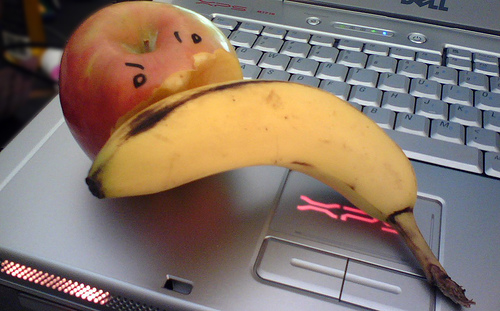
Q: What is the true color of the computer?
A: Gray.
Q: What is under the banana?
A: Laptop.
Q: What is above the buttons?
A: Touchpad.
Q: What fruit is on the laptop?
A: Apple and banana.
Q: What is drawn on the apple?
A: Eyes.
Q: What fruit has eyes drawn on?
A: Apple.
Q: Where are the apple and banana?
A: On a laptop computer.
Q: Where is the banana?
A: Next to the apple.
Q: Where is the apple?
A: Left from banana.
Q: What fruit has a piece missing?
A: Apple.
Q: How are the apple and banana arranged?
A: Apple is biting banana.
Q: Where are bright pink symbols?
A: On the laptop touchpad.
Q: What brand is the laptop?
A: Dell.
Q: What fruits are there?
A: Banana/apple.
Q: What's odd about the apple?
A: Drawn on.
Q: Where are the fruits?
A: On laptop.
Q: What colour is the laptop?
A: Silver.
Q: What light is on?
A: Laptop light.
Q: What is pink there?
A: Letters.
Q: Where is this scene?
A: Bedroom.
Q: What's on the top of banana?
A: Stem.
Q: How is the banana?
A: Ripe.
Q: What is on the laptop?
A: An apple and a banana.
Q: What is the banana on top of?
A: The laptop's trackpad.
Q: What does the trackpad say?
A: XPS.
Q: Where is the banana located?
A: In front of the apple.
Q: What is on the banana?
A: Brown spots.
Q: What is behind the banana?
A: An apple.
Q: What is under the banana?
A: A laptop.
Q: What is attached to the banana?
A: The banana stem.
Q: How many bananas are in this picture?
A: One.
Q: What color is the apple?
A: Red.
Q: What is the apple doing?
A: Biting the banana.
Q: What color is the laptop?
A: Silver.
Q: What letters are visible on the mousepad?
A: XP.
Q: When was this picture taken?
A: During the day.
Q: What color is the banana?
A: Yellow.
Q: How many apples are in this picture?
A: One.